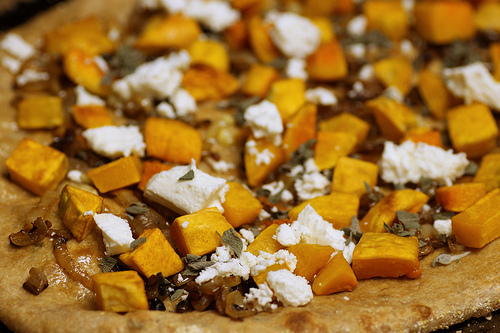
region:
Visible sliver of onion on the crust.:
[50, 229, 92, 289]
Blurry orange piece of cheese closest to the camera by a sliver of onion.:
[92, 269, 149, 311]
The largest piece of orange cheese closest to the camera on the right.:
[354, 228, 421, 281]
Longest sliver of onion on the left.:
[51, 225, 94, 292]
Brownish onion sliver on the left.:
[51, 227, 93, 292]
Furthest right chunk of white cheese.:
[441, 58, 498, 110]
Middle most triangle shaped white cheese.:
[246, 99, 285, 139]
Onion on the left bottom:
[52, 225, 95, 290]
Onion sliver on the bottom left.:
[53, 225, 91, 289]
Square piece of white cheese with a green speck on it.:
[146, 160, 227, 212]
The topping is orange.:
[117, 220, 184, 281]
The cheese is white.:
[265, 207, 351, 267]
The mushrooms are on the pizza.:
[165, 274, 257, 316]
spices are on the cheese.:
[173, 160, 206, 187]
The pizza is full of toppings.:
[5, 0, 495, 327]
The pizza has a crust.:
[4, 13, 489, 332]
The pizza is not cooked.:
[3, 0, 489, 327]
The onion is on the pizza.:
[43, 230, 97, 292]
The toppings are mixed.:
[0, 1, 495, 331]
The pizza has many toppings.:
[1, 0, 496, 330]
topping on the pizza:
[240, 148, 276, 185]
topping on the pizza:
[283, 223, 323, 255]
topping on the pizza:
[362, 168, 410, 208]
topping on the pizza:
[111, 114, 145, 140]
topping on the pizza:
[369, 99, 414, 151]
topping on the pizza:
[351, 68, 398, 111]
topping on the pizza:
[281, 257, 325, 292]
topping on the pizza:
[161, 215, 190, 257]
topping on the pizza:
[272, 97, 326, 142]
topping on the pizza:
[228, 280, 269, 316]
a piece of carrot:
[341, 217, 428, 290]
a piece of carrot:
[315, 240, 352, 304]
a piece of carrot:
[127, 230, 179, 293]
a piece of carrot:
[170, 213, 255, 268]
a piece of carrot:
[90, 263, 150, 327]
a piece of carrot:
[226, 122, 281, 194]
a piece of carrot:
[1, 129, 64, 184]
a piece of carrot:
[256, 58, 307, 107]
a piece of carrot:
[362, 93, 419, 142]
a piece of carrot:
[444, 81, 499, 169]